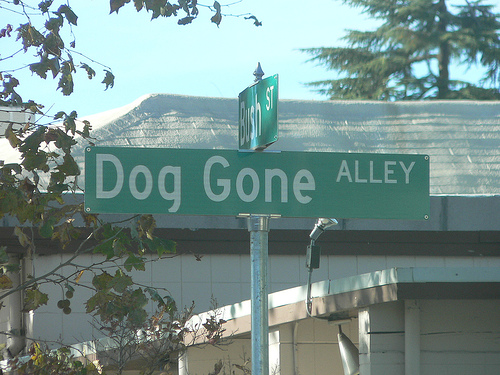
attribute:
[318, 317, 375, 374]
lamp — silver, light, facing down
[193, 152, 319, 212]
gone — word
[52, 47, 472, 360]
signs — green, street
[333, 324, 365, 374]
light fixture — exterior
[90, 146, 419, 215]
sign — green, white, metal, street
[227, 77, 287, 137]
sign — green, white, metal, street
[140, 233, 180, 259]
leaf — green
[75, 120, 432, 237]
street sign — green, dog gone alley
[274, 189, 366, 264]
floodlamp — exterior, lighting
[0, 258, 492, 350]
wall — gray, cement, block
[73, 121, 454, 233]
sign — green, white, road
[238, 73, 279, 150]
sign — bush st, road, small, street, indicating Bush Street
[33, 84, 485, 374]
street — corner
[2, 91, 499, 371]
white building — in background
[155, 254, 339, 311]
wall — white, brick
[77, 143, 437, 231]
sign — green, white, street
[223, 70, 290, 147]
sign — green, white, street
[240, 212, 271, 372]
pole — metal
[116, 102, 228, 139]
shingles — gray, asphalt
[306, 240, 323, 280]
conduit — wiring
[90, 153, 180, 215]
word — dog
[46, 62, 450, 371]
corner — street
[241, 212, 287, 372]
pole — grey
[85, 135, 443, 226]
sign — street, Dog Gone Alley, v